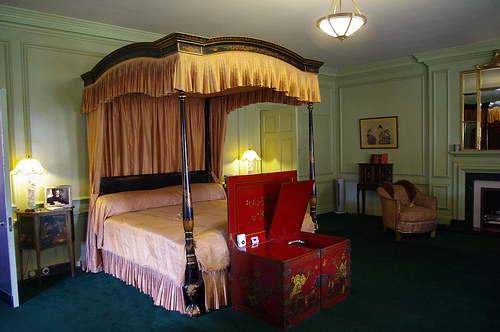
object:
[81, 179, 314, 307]
bed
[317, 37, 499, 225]
wall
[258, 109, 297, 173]
door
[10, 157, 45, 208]
lamp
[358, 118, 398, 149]
painting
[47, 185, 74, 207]
frame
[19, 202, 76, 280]
table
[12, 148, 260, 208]
lamps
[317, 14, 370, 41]
light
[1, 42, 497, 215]
carpet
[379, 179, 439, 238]
chair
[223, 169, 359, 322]
chest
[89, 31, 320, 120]
canopy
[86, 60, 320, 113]
ruffle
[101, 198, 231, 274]
bedspread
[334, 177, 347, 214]
heater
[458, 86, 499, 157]
mirror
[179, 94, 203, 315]
posts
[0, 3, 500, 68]
ceiling